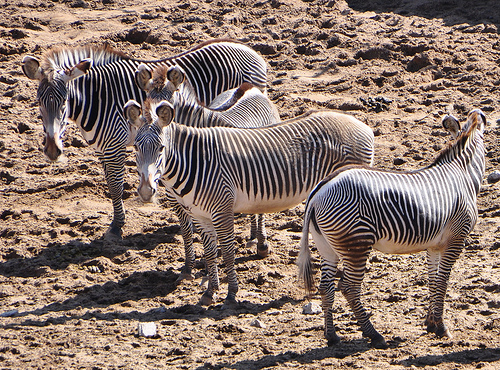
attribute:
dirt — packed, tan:
[20, 239, 376, 368]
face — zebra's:
[101, 94, 190, 212]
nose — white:
[127, 180, 159, 207]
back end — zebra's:
[284, 150, 375, 270]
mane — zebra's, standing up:
[30, 39, 128, 80]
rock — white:
[113, 308, 163, 345]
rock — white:
[301, 291, 328, 323]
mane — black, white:
[38, 46, 117, 72]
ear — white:
[13, 46, 53, 84]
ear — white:
[65, 63, 96, 85]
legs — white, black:
[406, 231, 481, 347]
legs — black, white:
[298, 249, 352, 354]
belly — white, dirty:
[376, 236, 447, 258]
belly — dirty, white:
[231, 192, 315, 217]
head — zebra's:
[101, 90, 188, 205]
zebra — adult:
[17, 34, 483, 361]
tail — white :
[285, 196, 326, 300]